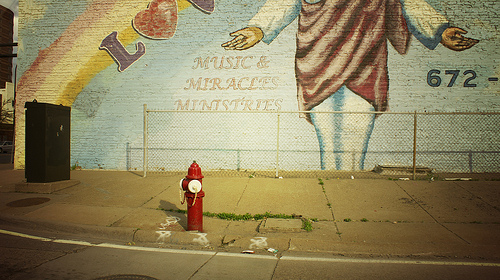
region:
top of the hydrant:
[183, 163, 205, 180]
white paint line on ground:
[300, 246, 369, 268]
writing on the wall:
[180, 50, 300, 114]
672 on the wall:
[425, 67, 482, 91]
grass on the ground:
[233, 209, 309, 239]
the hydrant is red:
[183, 194, 206, 233]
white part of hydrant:
[178, 179, 203, 192]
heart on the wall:
[132, 2, 179, 48]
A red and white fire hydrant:
[178, 160, 211, 236]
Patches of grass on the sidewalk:
[157, 202, 369, 236]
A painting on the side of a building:
[13, 2, 498, 173]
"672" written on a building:
[422, 64, 482, 96]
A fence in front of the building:
[138, 99, 498, 176]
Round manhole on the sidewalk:
[6, 190, 51, 214]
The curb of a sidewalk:
[1, 211, 499, 264]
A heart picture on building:
[129, 2, 185, 45]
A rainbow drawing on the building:
[14, 1, 194, 170]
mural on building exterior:
[14, 2, 497, 172]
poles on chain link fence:
[141, 107, 495, 176]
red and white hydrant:
[179, 160, 204, 230]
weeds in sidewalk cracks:
[158, 207, 311, 229]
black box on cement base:
[17, 101, 78, 192]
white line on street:
[1, 228, 498, 268]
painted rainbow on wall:
[16, 2, 183, 164]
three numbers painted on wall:
[426, 68, 477, 88]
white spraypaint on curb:
[156, 230, 267, 251]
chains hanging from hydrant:
[177, 190, 197, 206]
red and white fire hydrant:
[172, 155, 216, 237]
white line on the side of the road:
[0, 224, 499, 271]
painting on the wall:
[11, 0, 499, 183]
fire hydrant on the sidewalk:
[178, 158, 210, 236]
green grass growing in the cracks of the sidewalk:
[168, 204, 316, 231]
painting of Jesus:
[223, 2, 487, 172]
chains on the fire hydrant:
[171, 183, 203, 209]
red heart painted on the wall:
[128, 0, 185, 44]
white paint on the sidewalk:
[148, 205, 278, 252]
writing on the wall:
[171, 50, 289, 123]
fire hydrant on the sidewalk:
[171, 160, 218, 232]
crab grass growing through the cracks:
[217, 209, 319, 236]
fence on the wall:
[136, 100, 498, 192]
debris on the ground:
[234, 243, 284, 260]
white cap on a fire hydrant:
[187, 182, 203, 194]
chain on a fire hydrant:
[168, 185, 210, 207]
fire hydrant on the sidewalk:
[161, 161, 223, 237]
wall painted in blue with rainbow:
[10, 5, 499, 176]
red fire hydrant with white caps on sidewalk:
[178, 160, 210, 236]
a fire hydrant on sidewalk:
[146, 171, 214, 256]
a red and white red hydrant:
[163, 146, 242, 275]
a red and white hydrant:
[180, 154, 222, 244]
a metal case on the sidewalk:
[13, 86, 83, 161]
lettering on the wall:
[253, 88, 273, 105]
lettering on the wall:
[238, 103, 257, 120]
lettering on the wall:
[218, 96, 237, 109]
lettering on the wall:
[199, 97, 233, 118]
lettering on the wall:
[245, 73, 268, 96]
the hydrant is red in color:
[176, 160, 208, 228]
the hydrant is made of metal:
[176, 163, 205, 228]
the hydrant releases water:
[181, 161, 207, 228]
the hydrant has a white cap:
[187, 179, 202, 194]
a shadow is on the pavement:
[158, 198, 193, 237]